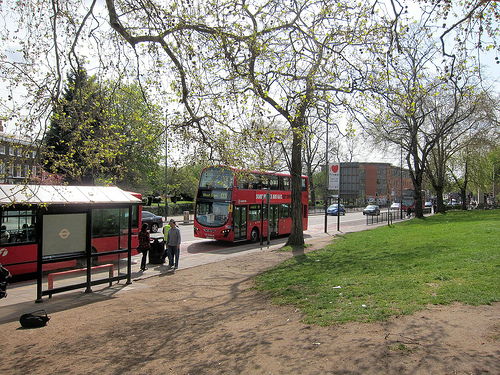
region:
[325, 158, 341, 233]
A white sign with a red heart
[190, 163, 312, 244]
A red couble-decker bus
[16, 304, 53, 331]
A backpack on the ground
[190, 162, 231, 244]
The front of a double-decker bus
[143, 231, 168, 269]
A garbage can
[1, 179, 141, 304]
A bus stop covering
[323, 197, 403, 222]
3 cars in the distance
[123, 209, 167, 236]
A dark car across the street from the buses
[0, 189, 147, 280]
A red single-level red bus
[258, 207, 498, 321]
A green grass open area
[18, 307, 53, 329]
black backpack near sidewalk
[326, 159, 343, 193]
white and red banner on pole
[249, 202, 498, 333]
patch of green grass next to sidewalk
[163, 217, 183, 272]
man in gray shirt walking down gray concrete sidewalk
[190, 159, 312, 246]
red double-decker bus parked near sidewalk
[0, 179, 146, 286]
red bus stopped at bus stop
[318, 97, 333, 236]
tall light post on edge of sidewalk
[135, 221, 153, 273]
woman with purse walking on sidewalk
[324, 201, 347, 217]
blue car stopped along side of a street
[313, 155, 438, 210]
rectangular red brick building next to street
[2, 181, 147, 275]
A red bus is parked.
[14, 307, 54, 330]
Black bag sitting on the ground.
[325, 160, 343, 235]
White sign with a heart on it.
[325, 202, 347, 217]
Blue car parked on the side of the road.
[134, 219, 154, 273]
Woman is wearing a checkered coat.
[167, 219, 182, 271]
The man is wearing blue jeans.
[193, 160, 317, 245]
A red double decker bus.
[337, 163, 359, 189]
Windows on a building.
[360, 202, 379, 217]
Black car driving on the road.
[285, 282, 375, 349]
Trash is lying on the ground.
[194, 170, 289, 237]
this is a twin bus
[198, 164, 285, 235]
the bus is red in color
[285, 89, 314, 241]
this is a tree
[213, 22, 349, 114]
the tree is branchy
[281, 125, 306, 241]
the tree is tall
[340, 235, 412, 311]
the grass is short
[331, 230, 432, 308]
the grass is green in color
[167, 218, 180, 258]
this is a man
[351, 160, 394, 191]
this is a building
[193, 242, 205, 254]
the road is tarmacked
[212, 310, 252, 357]
part of a ground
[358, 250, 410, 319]
part of a ground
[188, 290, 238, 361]
part of a shade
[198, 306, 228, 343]
part of a shade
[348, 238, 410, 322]
part of a field